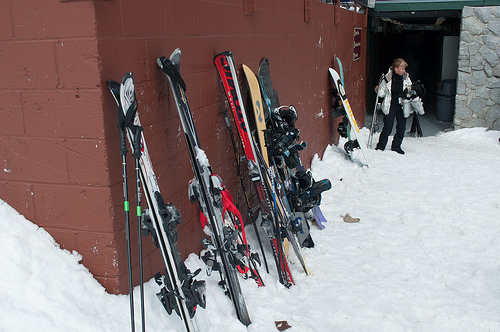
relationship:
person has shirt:
[374, 58, 425, 155] [386, 74, 404, 115]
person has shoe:
[374, 58, 425, 155] [372, 130, 387, 148]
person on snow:
[374, 58, 425, 155] [0, 127, 499, 329]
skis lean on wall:
[333, 56, 365, 169] [0, 0, 370, 293]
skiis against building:
[94, 40, 359, 330] [3, 2, 497, 298]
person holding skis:
[374, 58, 425, 155] [368, 69, 388, 156]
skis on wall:
[154, 46, 262, 329] [0, 0, 370, 293]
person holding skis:
[374, 58, 425, 155] [398, 80, 423, 133]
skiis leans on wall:
[106, 47, 372, 331] [0, 0, 370, 293]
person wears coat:
[374, 58, 425, 155] [365, 56, 428, 128]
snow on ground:
[380, 197, 456, 253] [3, 239, 492, 319]